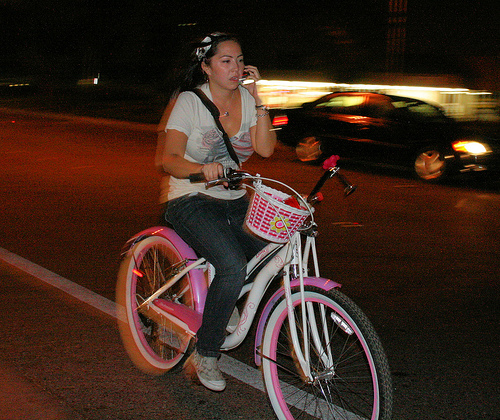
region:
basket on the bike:
[253, 190, 303, 242]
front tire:
[373, 354, 398, 380]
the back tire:
[116, 265, 136, 282]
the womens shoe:
[196, 357, 226, 394]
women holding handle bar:
[198, 165, 231, 181]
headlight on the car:
[455, 139, 494, 156]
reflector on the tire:
[331, 318, 356, 338]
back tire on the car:
[294, 134, 320, 160]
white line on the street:
[82, 284, 101, 313]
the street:
[366, 236, 467, 313]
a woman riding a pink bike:
[107, 36, 389, 396]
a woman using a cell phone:
[200, 43, 260, 102]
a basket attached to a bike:
[225, 179, 319, 261]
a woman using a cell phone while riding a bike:
[165, 23, 280, 298]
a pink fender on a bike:
[243, 273, 343, 408]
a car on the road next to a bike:
[188, 71, 473, 328]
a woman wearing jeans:
[195, 195, 232, 287]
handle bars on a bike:
[203, 154, 360, 213]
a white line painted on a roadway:
[20, 237, 278, 416]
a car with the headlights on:
[398, 116, 488, 176]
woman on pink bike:
[160, 48, 305, 343]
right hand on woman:
[176, 152, 259, 208]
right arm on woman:
[171, 108, 216, 200]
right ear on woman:
[196, 65, 212, 81]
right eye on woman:
[214, 50, 233, 68]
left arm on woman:
[237, 66, 282, 156]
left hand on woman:
[240, 68, 276, 105]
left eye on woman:
[233, 50, 247, 65]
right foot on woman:
[191, 340, 241, 414]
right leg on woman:
[176, 216, 290, 380]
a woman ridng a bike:
[72, 31, 497, 398]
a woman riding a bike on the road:
[69, 54, 470, 409]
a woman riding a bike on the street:
[37, 26, 497, 419]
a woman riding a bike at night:
[79, 63, 451, 411]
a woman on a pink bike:
[137, 75, 446, 415]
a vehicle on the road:
[285, 33, 492, 199]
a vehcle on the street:
[241, 26, 490, 287]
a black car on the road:
[267, 46, 463, 254]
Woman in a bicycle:
[128, 23, 395, 413]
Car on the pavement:
[282, 74, 494, 209]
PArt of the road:
[446, 355, 487, 419]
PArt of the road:
[418, 255, 460, 292]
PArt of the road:
[401, 303, 440, 398]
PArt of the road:
[57, 334, 107, 380]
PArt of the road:
[42, 210, 114, 270]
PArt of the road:
[100, 170, 187, 238]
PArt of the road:
[105, 116, 145, 158]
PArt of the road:
[28, 113, 78, 167]